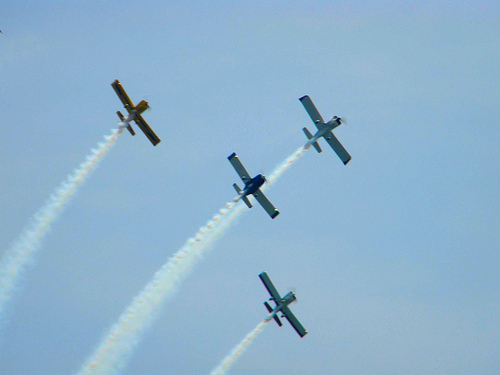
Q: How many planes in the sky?
A: Four.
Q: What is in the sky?
A: Airplanes.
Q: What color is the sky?
A: Blue.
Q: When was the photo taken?
A: Daytime.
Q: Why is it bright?
A: Sunny.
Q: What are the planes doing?
A: Flying.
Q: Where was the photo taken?
A: Under planes.